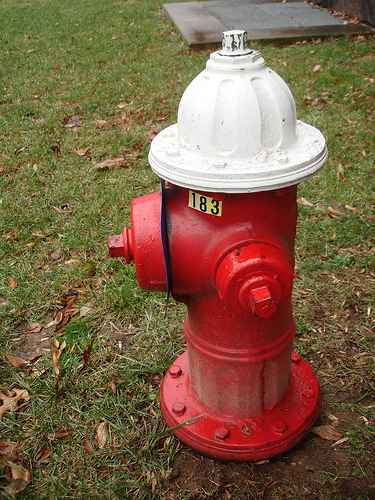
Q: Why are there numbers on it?
A: Identification.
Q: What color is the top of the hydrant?
A: White.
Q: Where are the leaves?
A: In the grass.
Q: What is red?
A: Hydrant.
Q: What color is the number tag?
A: Black and yellow.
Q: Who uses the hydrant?
A: Firemen.